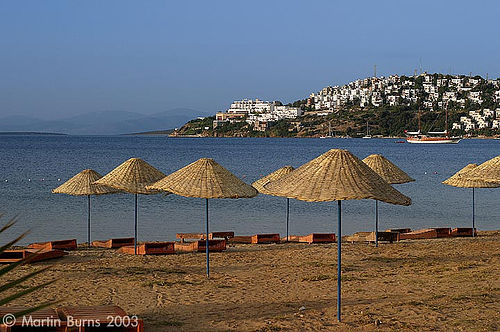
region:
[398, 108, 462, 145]
orange and white boat floating in ocean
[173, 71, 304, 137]
whit building on hillside of ocean island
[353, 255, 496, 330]
sand along the ocean line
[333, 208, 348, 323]
blue umbrella pole held fast by sand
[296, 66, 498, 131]
multiple houses on a hill on an ocean island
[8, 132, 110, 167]
calm blue ocean waters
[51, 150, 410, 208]
top of sunbrellas on ocean front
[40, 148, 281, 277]
sunbrellas and sun bathing pallets on sandy beach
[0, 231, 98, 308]
green tree leaves and sun pallets on sandy beach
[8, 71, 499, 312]
sandy blue ocean beach front with a view of mountainous island and sea port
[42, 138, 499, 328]
Many straw umbrellas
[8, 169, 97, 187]
A rope in the water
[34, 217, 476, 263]
Several lounge chairs are emty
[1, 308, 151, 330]
Name of photographer in white letters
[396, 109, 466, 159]
a large sail boat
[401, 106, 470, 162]
a boat sits on the water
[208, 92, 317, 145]
A large white building across the water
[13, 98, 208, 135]
mountains seen in the distance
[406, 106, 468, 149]
A red and white boat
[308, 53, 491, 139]
many white buildings on a hill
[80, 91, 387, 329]
the beach is clear and calm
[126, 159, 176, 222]
the beach is clear and calm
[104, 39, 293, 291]
the beach is clear and calm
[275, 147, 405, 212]
UMBRELLA IS MADE OF STRAW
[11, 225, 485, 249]
MULTIPLE CHAIRS FOR BEACH GOERS TO LAY ON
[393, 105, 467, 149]
LARGE DOUBLE MAST SHIP IN WATER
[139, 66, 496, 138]
LOTS OF BUILDINGS IN THE HILLS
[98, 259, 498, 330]
THE BEACH CONSISTS OF LOTS OF SAND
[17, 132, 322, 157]
WATER IS BLUE AND CRISP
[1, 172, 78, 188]
CRAB TRAPS ARE IN THE WATER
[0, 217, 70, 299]
PALM TREE IN THE LEFT MIDDLE OF PICTURE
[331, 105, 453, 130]
GREEN BUSHES ON THE MOUNTAIN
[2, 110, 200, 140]
MOUNTAINS ARE IN THE BACKGROUND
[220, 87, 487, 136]
a city on a hilltop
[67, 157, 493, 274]
a row of beach umbrellas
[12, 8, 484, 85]
a patch of clear blue sky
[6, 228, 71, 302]
the corner of a green plant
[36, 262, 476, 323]
a flat stretch of sand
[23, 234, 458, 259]
a row of empty beach chairs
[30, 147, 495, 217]
a stretch of flat ocean water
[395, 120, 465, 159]
a boat sailing in the ocean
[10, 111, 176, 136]
hazy mountains in the distance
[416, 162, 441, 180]
people swimming in the water